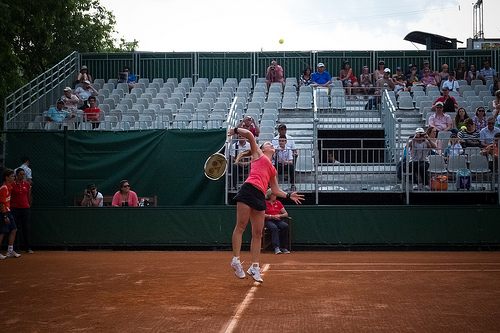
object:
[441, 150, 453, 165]
ground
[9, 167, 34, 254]
person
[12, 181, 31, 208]
shirt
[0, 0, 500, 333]
stadium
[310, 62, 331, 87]
man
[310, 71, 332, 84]
blue shirt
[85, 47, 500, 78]
fabric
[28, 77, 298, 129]
seats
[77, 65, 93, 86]
person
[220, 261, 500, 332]
lines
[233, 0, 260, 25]
umbrella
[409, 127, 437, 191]
person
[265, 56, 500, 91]
people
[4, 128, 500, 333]
tennis match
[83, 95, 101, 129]
person watching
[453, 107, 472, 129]
woman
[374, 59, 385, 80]
woman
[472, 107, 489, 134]
woman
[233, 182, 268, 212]
skirt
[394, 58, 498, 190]
spectators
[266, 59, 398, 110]
spectators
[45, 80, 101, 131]
spectators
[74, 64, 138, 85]
spectators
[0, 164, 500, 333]
match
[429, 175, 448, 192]
bag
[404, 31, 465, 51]
slanted structure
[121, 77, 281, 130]
chairs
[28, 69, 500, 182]
bleachers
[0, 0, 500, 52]
sky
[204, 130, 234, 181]
racket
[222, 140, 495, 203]
railing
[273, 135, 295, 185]
spectator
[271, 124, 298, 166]
spectator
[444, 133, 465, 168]
spectator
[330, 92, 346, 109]
seat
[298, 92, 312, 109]
seat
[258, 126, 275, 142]
seat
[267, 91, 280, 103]
seat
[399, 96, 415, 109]
seat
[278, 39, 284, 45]
air-born ball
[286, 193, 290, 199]
band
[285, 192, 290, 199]
wrist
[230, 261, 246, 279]
sneaker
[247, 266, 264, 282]
sneaker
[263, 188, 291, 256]
person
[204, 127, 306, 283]
person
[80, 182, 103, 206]
people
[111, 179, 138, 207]
people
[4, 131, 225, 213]
wall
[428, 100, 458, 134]
person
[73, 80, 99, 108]
person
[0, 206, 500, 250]
partition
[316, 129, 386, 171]
passageway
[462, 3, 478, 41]
columns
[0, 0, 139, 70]
tree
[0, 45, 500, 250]
stands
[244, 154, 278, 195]
top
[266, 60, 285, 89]
person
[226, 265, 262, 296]
mid-jump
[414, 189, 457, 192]
floor